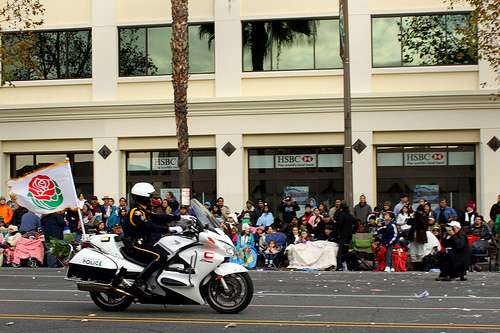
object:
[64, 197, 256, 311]
motorcycle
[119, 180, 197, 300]
officer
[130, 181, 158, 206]
helmet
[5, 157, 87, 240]
flag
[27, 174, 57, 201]
rose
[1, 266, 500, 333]
road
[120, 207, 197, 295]
uniform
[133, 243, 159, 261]
stripe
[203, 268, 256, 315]
tire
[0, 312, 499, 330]
stripe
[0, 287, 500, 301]
stripe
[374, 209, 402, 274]
people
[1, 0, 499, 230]
building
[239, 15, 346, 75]
window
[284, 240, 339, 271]
blanket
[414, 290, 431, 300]
debris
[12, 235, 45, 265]
blanket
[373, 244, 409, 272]
coat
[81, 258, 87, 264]
p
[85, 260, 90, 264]
o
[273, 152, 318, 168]
sign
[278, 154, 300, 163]
hsbc